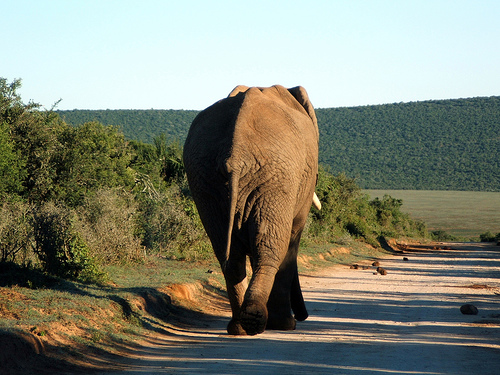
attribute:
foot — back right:
[237, 298, 270, 339]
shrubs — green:
[5, 96, 71, 250]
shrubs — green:
[38, 112, 110, 300]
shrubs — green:
[86, 116, 151, 266]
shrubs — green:
[135, 129, 207, 252]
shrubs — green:
[318, 155, 404, 232]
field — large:
[356, 189, 498, 241]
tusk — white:
[312, 186, 327, 209]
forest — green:
[55, 107, 194, 150]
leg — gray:
[244, 209, 291, 331]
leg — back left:
[179, 179, 254, 343]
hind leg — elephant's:
[194, 205, 250, 334]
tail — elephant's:
[219, 177, 240, 277]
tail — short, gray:
[223, 157, 240, 259]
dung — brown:
[345, 259, 391, 276]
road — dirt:
[103, 242, 492, 371]